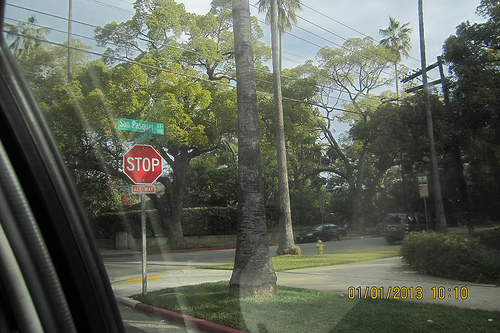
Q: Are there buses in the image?
A: No, there are no buses.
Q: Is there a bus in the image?
A: No, there are no buses.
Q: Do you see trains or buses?
A: No, there are no buses or trains.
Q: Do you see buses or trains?
A: No, there are no buses or trains.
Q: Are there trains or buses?
A: No, there are no buses or trains.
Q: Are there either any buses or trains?
A: No, there are no buses or trains.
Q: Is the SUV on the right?
A: Yes, the SUV is on the right of the image.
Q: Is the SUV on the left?
A: No, the SUV is on the right of the image.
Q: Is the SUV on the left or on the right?
A: The SUV is on the right of the image.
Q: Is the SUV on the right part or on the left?
A: The SUV is on the right of the image.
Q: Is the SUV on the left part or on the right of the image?
A: The SUV is on the right of the image.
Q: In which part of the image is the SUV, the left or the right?
A: The SUV is on the right of the image.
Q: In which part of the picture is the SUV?
A: The SUV is on the right of the image.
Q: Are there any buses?
A: No, there are no buses.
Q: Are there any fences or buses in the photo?
A: No, there are no fences or buses.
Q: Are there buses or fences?
A: No, there are no fences or buses.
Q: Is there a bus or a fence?
A: No, there are no fences or buses.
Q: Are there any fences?
A: No, there are no fences.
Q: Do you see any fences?
A: No, there are no fences.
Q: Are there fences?
A: No, there are no fences.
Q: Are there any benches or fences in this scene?
A: No, there are no fences or benches.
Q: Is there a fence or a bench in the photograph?
A: No, there are no fences or benches.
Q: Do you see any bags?
A: No, there are no bags.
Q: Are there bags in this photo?
A: No, there are no bags.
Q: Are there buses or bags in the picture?
A: No, there are no bags or buses.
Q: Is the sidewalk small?
A: Yes, the sidewalk is small.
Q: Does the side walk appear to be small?
A: Yes, the side walk is small.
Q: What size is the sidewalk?
A: The sidewalk is small.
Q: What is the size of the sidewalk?
A: The sidewalk is small.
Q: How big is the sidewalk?
A: The sidewalk is small.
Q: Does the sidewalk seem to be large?
A: No, the sidewalk is small.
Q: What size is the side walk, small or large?
A: The side walk is small.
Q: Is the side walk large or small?
A: The side walk is small.